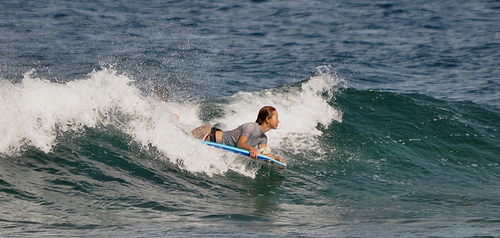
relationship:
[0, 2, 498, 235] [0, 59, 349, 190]
water on wave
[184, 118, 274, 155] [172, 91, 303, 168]
suit on woman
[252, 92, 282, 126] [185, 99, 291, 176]
hair of woman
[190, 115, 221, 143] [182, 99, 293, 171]
pants on woman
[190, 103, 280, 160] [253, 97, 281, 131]
woman with hair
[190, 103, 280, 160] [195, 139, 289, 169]
woman on board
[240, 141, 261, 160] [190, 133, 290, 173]
hand gripping surfboard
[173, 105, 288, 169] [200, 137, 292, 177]
man lying on surfboard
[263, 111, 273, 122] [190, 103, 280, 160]
ear on woman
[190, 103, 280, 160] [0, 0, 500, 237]
woman surfing in ocean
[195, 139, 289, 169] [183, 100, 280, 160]
board under woman